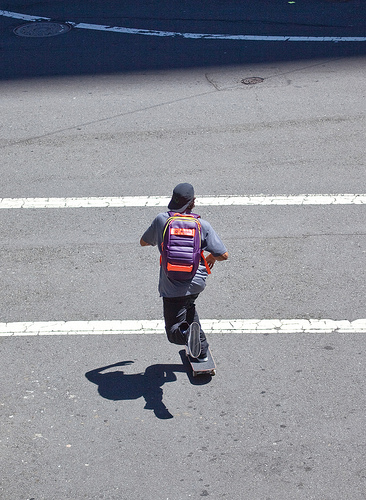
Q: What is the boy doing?
A: Skateboarding.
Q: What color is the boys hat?
A: Black.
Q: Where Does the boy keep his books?
A: Backpack.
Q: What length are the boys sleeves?
A: Short.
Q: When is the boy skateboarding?
A: Daytime.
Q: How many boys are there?
A: One.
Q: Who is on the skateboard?
A: The boy.